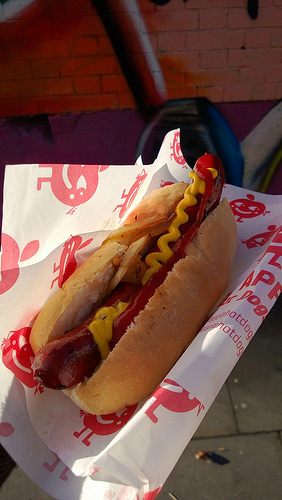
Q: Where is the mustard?
A: On hot dog.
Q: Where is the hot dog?
A: In bun.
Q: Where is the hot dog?
A: On paper.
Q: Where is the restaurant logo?
A: On paper.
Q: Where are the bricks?
A: In wall.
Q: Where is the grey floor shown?
A: Under hot dog.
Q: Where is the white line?
A: On the wall.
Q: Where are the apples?
A: On paper.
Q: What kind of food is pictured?
A: A hot dog.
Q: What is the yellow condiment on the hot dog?
A: Mustard.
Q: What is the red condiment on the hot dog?
A: Ketchup.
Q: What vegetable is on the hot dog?
A: Onions.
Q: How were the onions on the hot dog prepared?
A: Roasted.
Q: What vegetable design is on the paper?
A: Tomatoes.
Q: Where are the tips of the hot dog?
A: Sticking out of the bun.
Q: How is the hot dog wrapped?
A: In paper.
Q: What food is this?
A: A hotdog.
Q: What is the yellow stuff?
A: Mustard.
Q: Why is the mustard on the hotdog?
A: To add flavor.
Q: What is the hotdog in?
A: A bug.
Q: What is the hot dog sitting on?
A: A wrapper.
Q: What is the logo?
A: An apple.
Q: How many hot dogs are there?
A: 1.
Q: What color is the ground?
A: Gray.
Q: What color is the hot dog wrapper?
A: Red and white.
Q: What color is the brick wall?
A: Red.